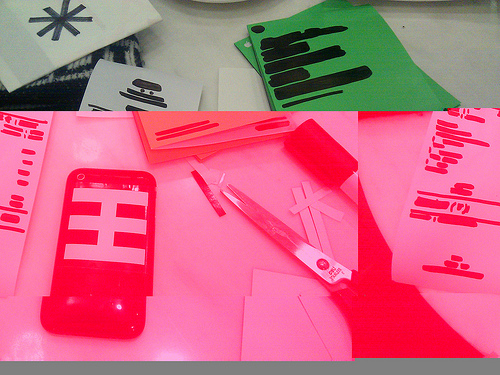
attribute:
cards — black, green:
[250, 11, 454, 111]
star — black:
[28, 2, 91, 42]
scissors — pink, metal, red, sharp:
[215, 185, 431, 356]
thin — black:
[190, 172, 226, 217]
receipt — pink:
[392, 108, 498, 291]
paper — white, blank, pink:
[241, 267, 344, 360]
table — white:
[8, 321, 256, 361]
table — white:
[402, 13, 500, 61]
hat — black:
[3, 36, 152, 104]